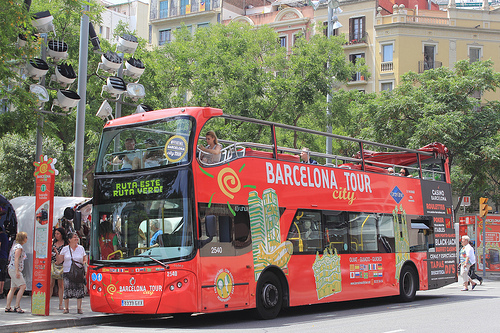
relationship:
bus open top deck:
[84, 103, 462, 330] [98, 100, 454, 184]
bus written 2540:
[84, 103, 462, 330] [207, 242, 228, 259]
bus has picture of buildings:
[84, 103, 462, 330] [238, 176, 418, 302]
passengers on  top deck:
[119, 123, 421, 181] [98, 100, 454, 184]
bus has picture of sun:
[84, 103, 462, 330] [194, 149, 263, 221]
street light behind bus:
[7, 4, 154, 134] [84, 103, 462, 330]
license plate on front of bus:
[117, 298, 145, 309] [85, 107, 204, 315]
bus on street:
[84, 103, 462, 330] [14, 274, 498, 333]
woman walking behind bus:
[454, 233, 486, 294] [84, 103, 462, 330]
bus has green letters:
[84, 103, 462, 330] [111, 178, 169, 200]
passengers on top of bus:
[119, 123, 421, 181] [84, 103, 462, 330]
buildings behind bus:
[103, 1, 499, 83] [84, 103, 462, 330]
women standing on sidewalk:
[54, 227, 87, 321] [2, 286, 94, 329]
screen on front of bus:
[85, 107, 204, 315] [84, 103, 462, 330]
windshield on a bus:
[85, 107, 204, 315] [84, 103, 462, 330]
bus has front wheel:
[84, 103, 462, 330] [249, 264, 291, 322]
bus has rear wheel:
[84, 103, 462, 330] [392, 257, 424, 303]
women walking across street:
[454, 233, 486, 294] [14, 274, 498, 333]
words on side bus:
[263, 150, 378, 203] [84, 103, 462, 330]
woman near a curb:
[54, 227, 87, 321] [10, 304, 90, 332]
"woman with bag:
[54, 227, 87, 321] [66, 241, 90, 287]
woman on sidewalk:
[54, 227, 87, 321] [2, 286, 94, 329]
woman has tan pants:
[454, 233, 486, 294] [460, 264, 475, 288]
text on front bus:
[111, 178, 169, 200] [84, 103, 462, 330]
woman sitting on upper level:
[197, 128, 224, 160] [98, 100, 454, 184]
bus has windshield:
[84, 103, 462, 330] [85, 107, 204, 315]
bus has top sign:
[84, 103, 462, 330] [161, 133, 188, 167]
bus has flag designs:
[84, 103, 462, 330] [344, 255, 390, 293]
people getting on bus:
[54, 227, 87, 321] [84, 103, 462, 330]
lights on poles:
[7, 4, 154, 134] [27, 8, 89, 187]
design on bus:
[194, 149, 263, 221] [84, 103, 462, 330]